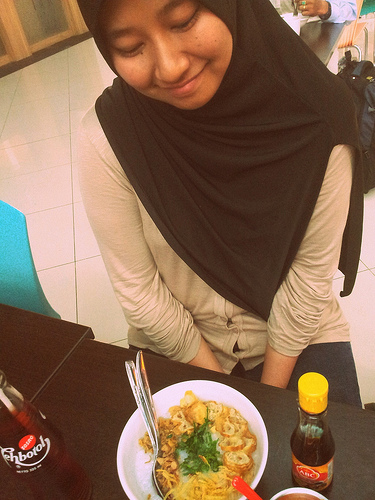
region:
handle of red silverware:
[226, 474, 264, 498]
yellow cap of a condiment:
[297, 369, 327, 412]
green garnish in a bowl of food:
[177, 413, 227, 481]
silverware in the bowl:
[118, 351, 177, 497]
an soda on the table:
[1, 360, 97, 497]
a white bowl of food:
[114, 376, 270, 499]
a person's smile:
[153, 58, 218, 103]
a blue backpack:
[340, 61, 374, 187]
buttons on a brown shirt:
[210, 296, 255, 364]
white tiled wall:
[2, 38, 136, 344]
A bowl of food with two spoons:
[99, 379, 277, 496]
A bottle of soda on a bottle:
[1, 370, 85, 494]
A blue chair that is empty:
[2, 201, 71, 319]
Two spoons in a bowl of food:
[122, 349, 169, 496]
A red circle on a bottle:
[7, 416, 45, 464]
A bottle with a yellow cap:
[297, 371, 330, 489]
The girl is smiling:
[102, 2, 229, 113]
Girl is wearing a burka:
[87, 2, 260, 152]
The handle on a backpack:
[336, 52, 374, 99]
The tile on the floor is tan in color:
[49, 249, 104, 307]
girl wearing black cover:
[45, 2, 373, 295]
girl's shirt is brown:
[63, 100, 370, 319]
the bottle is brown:
[289, 420, 352, 497]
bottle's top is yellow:
[287, 359, 354, 437]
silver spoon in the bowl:
[100, 336, 210, 489]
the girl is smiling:
[87, 7, 249, 109]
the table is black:
[17, 309, 341, 493]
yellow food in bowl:
[167, 393, 279, 489]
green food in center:
[165, 422, 243, 498]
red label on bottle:
[289, 453, 332, 489]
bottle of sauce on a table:
[283, 366, 338, 490]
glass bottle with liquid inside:
[1, 366, 99, 498]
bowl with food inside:
[96, 375, 273, 498]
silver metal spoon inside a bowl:
[124, 349, 173, 498]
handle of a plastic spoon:
[233, 472, 265, 499]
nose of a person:
[153, 41, 191, 84]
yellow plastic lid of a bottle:
[294, 371, 330, 412]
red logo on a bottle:
[17, 433, 36, 452]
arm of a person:
[251, 82, 366, 392]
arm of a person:
[72, 107, 225, 377]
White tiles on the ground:
[8, 79, 74, 188]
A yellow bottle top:
[297, 370, 328, 414]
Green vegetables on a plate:
[189, 430, 213, 465]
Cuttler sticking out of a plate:
[117, 346, 165, 498]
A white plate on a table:
[116, 373, 269, 498]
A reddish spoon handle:
[228, 472, 264, 498]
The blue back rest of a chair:
[1, 200, 30, 305]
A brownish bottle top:
[65, 369, 116, 437]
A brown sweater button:
[230, 327, 240, 335]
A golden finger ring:
[302, 4, 306, 11]